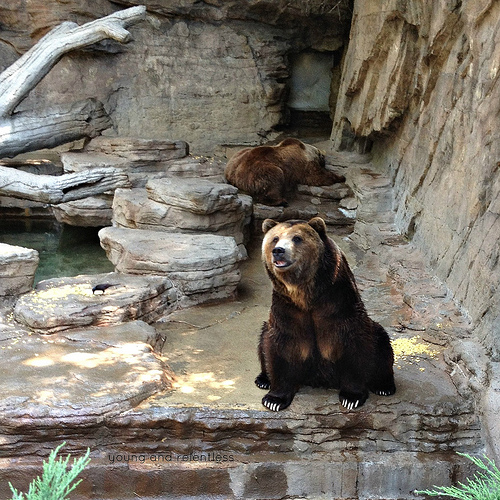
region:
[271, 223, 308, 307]
This bear's face is quite large in the photo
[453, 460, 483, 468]
There is greenery around this bear's living quarters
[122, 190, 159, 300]
There is a large stone that is present here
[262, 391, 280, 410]
This bear has white claws that he is brandishing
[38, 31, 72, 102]
There is a large trunk of wood in the distance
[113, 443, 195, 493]
There is a phrase in this photo that says Young and Relentless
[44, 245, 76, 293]
There is a light pool of water in the area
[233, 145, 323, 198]
There is a second bear in this photo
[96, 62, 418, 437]
Jackson Mingus took this photo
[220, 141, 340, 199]
Bear sleeping in background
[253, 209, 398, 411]
Bear showin interest in picture being taken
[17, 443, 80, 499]
Pines in the foreground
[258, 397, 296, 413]
Claws on bear very white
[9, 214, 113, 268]
Small water pool for bears.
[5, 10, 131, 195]
Old tree branches to the side.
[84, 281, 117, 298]
Bird eating on the rock.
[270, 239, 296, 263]
White snout on the bear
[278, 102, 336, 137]
Cave for bears in the distant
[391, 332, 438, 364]
Bear food off to the side.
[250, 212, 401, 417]
Bear is sitting up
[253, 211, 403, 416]
Brown bear is sitting up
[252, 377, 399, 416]
Bear has claws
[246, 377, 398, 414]
Brown bear has claws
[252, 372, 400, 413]
Bear has long claws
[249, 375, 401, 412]
Brown bear has long claws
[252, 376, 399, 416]
Bear has white claws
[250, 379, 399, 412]
Brown bear has white claws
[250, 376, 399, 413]
Bear has long white claws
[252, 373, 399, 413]
Brown bear has long white claws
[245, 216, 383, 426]
Dark brown bear on rocks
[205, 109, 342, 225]
Dark brown bear on rocks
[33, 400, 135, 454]
Small rocks with water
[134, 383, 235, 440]
Small rocks with water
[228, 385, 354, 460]
Small rocks with water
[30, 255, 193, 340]
Small rocks with water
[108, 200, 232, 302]
Small rocks with water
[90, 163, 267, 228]
Small rocks with water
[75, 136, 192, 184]
Small rocks with water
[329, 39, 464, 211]
Small rocks with water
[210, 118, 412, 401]
Two bears are on rocks.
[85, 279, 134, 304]
A black bird is on a rock.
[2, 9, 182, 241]
A large log lies above water.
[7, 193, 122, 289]
A pond is beneath the rocks.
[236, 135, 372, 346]
The bears have brown fur.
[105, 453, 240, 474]
The words "young and restless" are printed.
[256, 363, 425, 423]
The bear has white claws.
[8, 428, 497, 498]
Green plants are at the rock's edge.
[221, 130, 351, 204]
The bear is laying down.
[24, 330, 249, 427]
Sunlight peeks through the shade.